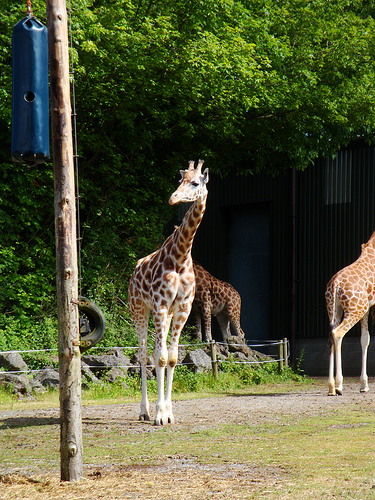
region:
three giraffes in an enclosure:
[105, 147, 370, 420]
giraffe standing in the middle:
[108, 144, 206, 425]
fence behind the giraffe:
[4, 339, 286, 396]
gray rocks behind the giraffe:
[1, 335, 272, 391]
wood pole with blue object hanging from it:
[45, 1, 86, 476]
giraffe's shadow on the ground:
[3, 405, 135, 429]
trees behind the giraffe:
[7, 0, 371, 355]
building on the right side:
[181, 135, 368, 368]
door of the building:
[227, 201, 270, 353]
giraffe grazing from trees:
[168, 232, 253, 353]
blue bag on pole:
[12, 22, 50, 153]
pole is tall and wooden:
[71, 416, 89, 461]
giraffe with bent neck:
[223, 298, 259, 368]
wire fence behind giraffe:
[12, 351, 53, 385]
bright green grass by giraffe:
[232, 363, 247, 387]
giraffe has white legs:
[151, 382, 186, 430]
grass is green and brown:
[216, 426, 262, 477]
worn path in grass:
[204, 395, 252, 430]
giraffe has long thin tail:
[329, 290, 340, 359]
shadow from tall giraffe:
[10, 411, 45, 456]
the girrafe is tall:
[116, 142, 259, 444]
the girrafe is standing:
[132, 151, 228, 435]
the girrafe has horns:
[151, 151, 226, 219]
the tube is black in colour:
[51, 271, 124, 357]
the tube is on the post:
[67, 281, 117, 344]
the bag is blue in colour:
[4, 5, 98, 175]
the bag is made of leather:
[12, 21, 57, 206]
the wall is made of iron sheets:
[286, 171, 363, 241]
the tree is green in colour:
[177, 24, 318, 164]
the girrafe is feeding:
[189, 250, 249, 336]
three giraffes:
[109, 173, 373, 443]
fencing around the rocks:
[2, 330, 290, 377]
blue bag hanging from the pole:
[5, 15, 61, 175]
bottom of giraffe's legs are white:
[133, 367, 185, 430]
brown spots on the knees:
[156, 352, 182, 372]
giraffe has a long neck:
[176, 154, 209, 265]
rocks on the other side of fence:
[4, 340, 284, 382]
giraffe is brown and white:
[203, 267, 236, 302]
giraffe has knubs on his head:
[185, 150, 208, 170]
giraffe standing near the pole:
[136, 151, 217, 433]